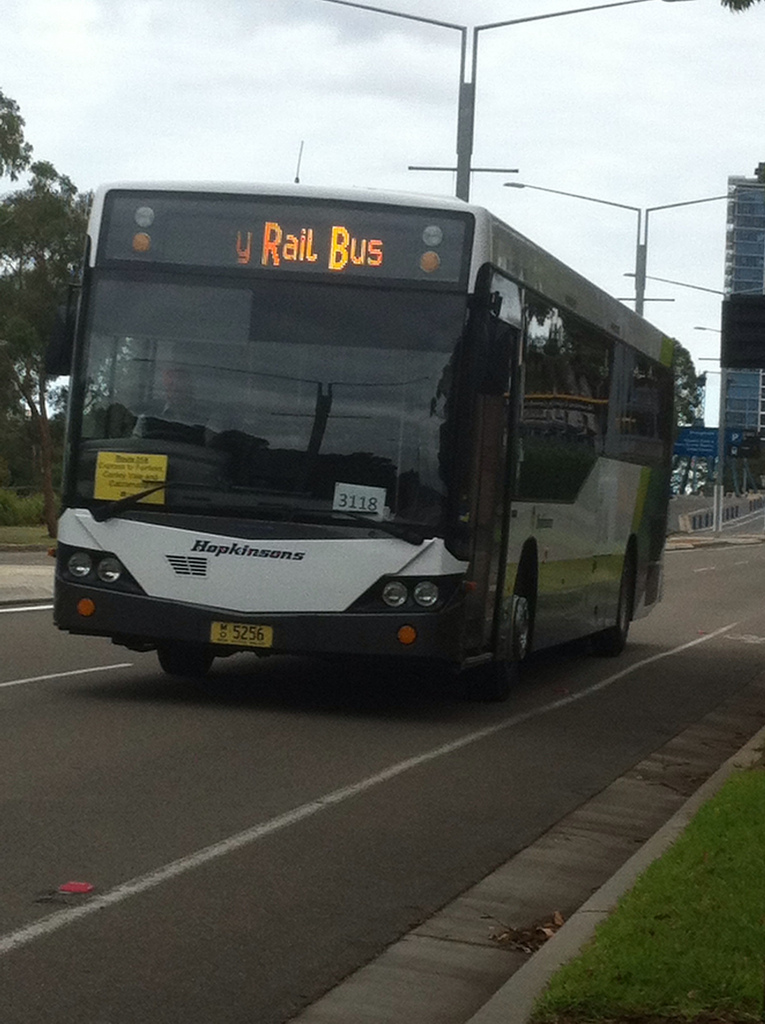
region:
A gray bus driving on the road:
[52, 181, 673, 702]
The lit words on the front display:
[231, 222, 386, 265]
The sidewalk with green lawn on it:
[468, 764, 761, 1020]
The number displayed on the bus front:
[332, 481, 386, 517]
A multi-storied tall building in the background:
[718, 159, 763, 494]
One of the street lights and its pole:
[505, 181, 764, 314]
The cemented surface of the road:
[3, 507, 762, 1021]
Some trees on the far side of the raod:
[1, 87, 93, 538]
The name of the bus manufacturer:
[192, 536, 303, 562]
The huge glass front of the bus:
[63, 273, 462, 516]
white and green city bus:
[81, 179, 673, 625]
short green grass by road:
[583, 791, 764, 998]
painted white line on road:
[161, 791, 298, 860]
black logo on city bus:
[189, 529, 322, 573]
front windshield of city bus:
[114, 265, 423, 449]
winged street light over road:
[388, 17, 535, 167]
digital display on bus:
[146, 201, 389, 282]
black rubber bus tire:
[497, 544, 522, 719]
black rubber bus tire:
[624, 532, 634, 642]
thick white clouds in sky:
[149, 20, 377, 124]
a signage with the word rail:
[257, 213, 322, 273]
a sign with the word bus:
[322, 215, 388, 277]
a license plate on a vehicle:
[193, 611, 294, 661]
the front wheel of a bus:
[483, 518, 549, 719]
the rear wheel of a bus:
[605, 529, 644, 664]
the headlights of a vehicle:
[39, 542, 479, 662]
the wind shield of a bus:
[78, 260, 474, 531]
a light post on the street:
[501, 166, 745, 322]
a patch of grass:
[621, 900, 754, 1011]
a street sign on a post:
[660, 418, 723, 461]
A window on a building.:
[725, 380, 759, 404]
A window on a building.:
[726, 397, 758, 410]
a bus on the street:
[48, 184, 676, 698]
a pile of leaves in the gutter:
[481, 911, 559, 952]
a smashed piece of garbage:
[58, 877, 89, 897]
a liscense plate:
[207, 618, 271, 646]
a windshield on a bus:
[70, 333, 454, 504]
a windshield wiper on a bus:
[89, 474, 227, 518]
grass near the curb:
[529, 759, 762, 1020]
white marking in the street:
[0, 616, 741, 959]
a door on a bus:
[457, 321, 522, 656]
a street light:
[502, 175, 758, 314]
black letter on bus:
[204, 542, 217, 552]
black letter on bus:
[211, 543, 229, 558]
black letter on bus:
[228, 539, 244, 559]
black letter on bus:
[236, 539, 253, 557]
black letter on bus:
[246, 543, 260, 558]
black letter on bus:
[257, 545, 271, 562]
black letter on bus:
[268, 545, 281, 561]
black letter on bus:
[275, 545, 291, 563]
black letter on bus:
[289, 546, 309, 564]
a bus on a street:
[49, 170, 675, 706]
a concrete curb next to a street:
[547, 772, 736, 971]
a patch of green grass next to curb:
[592, 764, 751, 1015]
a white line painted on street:
[242, 735, 485, 873]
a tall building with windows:
[719, 158, 762, 454]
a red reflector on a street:
[53, 870, 99, 907]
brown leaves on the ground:
[491, 890, 588, 966]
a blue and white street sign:
[672, 425, 720, 455]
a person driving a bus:
[127, 358, 216, 455]